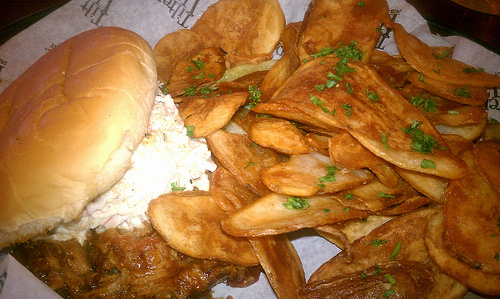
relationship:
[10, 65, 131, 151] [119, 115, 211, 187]
hamburger bun with white chicken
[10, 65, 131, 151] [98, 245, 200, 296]
hamburger bun with brown chicken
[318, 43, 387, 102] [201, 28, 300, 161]
green season on fries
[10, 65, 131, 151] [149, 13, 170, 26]
hamburger bun on wrap paper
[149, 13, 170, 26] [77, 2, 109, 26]
wrap paper has writing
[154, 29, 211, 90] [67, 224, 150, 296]
cheese on hamburger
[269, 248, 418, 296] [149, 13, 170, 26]
bacon on wrap paper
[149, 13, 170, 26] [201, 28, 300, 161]
wrap paper under fries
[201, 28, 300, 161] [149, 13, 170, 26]
fries on wrap paper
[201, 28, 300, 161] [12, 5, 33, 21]
fries on plate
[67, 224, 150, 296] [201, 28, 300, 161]
hamburger near fries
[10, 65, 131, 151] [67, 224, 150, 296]
hamburger bun of hamburger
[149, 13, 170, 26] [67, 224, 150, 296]
wrap paper under hamburger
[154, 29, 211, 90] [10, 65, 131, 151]
cheese under hamburger bun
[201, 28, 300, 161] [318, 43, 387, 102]
fries with green season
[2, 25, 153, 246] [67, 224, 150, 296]
bun for hamburger